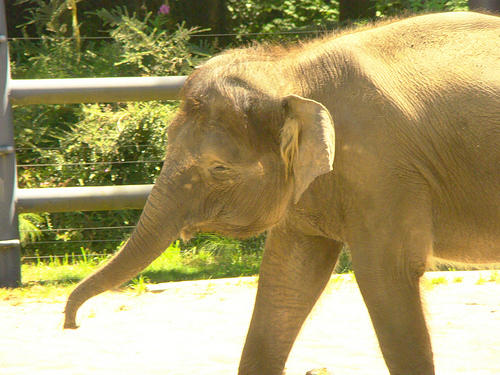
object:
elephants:
[203, 63, 402, 240]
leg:
[342, 218, 435, 374]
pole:
[0, 3, 23, 285]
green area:
[5, 2, 468, 291]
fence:
[0, 3, 184, 288]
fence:
[23, 74, 115, 206]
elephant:
[27, 10, 467, 374]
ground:
[0, 269, 499, 373]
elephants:
[59, 25, 488, 374]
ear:
[283, 92, 336, 206]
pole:
[12, 74, 186, 103]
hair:
[248, 41, 283, 62]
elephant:
[62, 11, 499, 373]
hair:
[223, 23, 369, 69]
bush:
[17, 99, 157, 265]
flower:
[158, 5, 174, 17]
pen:
[0, 31, 186, 287]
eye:
[205, 161, 236, 178]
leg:
[231, 236, 346, 373]